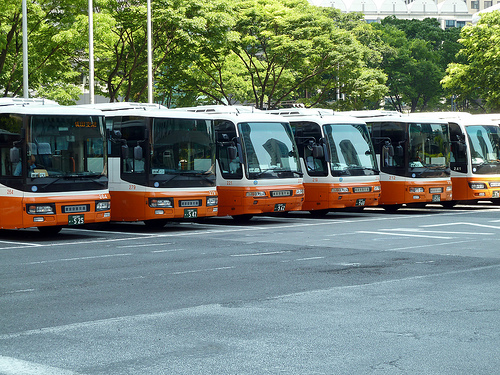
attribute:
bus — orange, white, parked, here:
[77, 103, 219, 231]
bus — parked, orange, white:
[261, 108, 382, 217]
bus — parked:
[179, 104, 303, 221]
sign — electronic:
[74, 120, 98, 130]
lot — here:
[4, 200, 498, 373]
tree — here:
[91, 2, 199, 102]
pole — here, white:
[146, 2, 153, 105]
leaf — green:
[124, 14, 127, 17]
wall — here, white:
[316, 0, 498, 26]